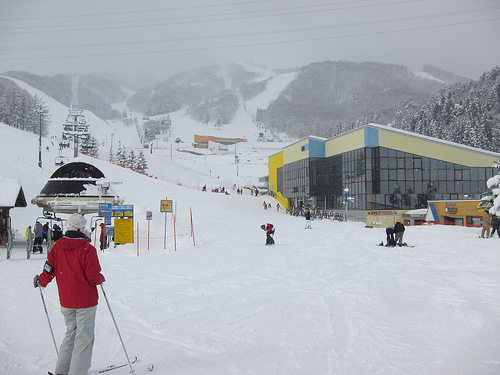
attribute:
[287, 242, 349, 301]
snow — white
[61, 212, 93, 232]
cap — white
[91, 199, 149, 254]
signs — blue, yellow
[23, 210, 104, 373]
skier — wearing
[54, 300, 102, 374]
pants — white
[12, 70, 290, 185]
snow — white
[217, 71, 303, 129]
mountain — distant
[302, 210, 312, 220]
jacket — black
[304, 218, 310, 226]
pants — white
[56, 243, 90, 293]
jacket — red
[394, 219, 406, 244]
skier — bent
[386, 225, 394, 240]
skier — bent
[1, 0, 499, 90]
sky — dark, gray, cloudy